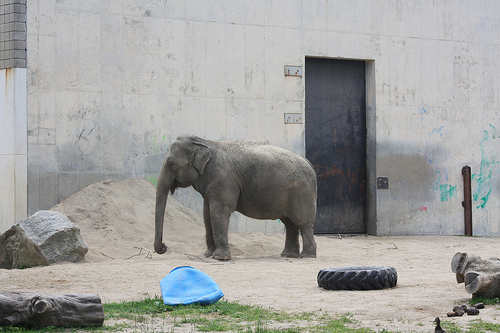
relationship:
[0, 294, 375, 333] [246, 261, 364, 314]
patch growing in dirt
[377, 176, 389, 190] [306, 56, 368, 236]
control panel near door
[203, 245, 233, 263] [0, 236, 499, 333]
feet placed in sand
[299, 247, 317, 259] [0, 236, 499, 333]
feet placed in sand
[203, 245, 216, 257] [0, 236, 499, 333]
feet placed in sand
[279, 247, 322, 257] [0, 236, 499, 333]
feet placed in sand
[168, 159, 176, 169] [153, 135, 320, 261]
eye of elephant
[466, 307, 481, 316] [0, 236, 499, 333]
elephant dung in dirt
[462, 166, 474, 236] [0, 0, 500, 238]
metal post against wall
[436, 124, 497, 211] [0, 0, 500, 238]
graffiti written on wall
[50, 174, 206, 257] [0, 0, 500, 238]
pile of sand against wall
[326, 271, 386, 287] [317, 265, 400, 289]
edge of tire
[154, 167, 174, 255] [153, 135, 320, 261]
trunk of elephant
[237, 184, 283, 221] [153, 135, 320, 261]
stomach of elephant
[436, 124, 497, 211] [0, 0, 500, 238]
graffiti on wall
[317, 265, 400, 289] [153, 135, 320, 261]
tire next to elephant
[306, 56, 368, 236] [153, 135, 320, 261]
door behind elephant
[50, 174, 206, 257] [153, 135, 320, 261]
pile of sand near elephant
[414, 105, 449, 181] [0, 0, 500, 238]
stuff on wall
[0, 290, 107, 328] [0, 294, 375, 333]
log on patch